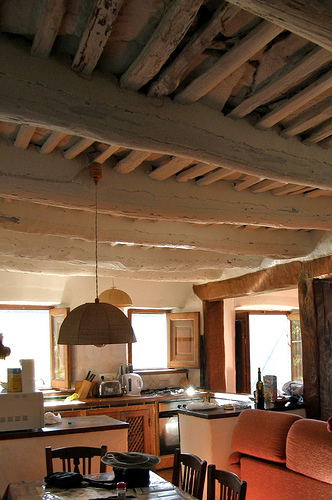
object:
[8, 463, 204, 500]
table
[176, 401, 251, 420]
counter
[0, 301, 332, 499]
kitchen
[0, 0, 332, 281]
ceiling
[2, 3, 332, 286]
logs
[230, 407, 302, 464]
cushions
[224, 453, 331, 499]
seat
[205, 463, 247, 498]
chair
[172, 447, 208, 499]
chair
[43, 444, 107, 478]
chair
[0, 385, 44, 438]
microwave oven